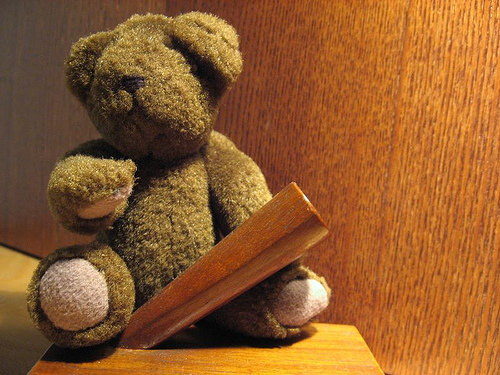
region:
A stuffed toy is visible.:
[95, 104, 209, 226]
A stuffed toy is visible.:
[55, 8, 210, 285]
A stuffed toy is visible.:
[54, 32, 175, 204]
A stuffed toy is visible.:
[91, 37, 203, 261]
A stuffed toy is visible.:
[107, 100, 192, 261]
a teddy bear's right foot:
[27, 244, 136, 351]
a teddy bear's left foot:
[252, 264, 329, 343]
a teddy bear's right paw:
[52, 155, 137, 233]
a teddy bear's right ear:
[65, 34, 114, 99]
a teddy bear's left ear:
[171, 6, 242, 93]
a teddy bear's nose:
[120, 73, 148, 95]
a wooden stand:
[30, 181, 387, 373]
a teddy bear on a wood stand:
[27, 9, 384, 374]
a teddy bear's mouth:
[110, 96, 170, 126]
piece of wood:
[122, 178, 328, 348]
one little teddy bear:
[28, 23, 402, 352]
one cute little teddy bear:
[17, 22, 390, 329]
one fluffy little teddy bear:
[18, 21, 381, 349]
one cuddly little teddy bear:
[22, 18, 407, 348]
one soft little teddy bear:
[0, 17, 395, 352]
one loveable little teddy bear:
[30, 10, 396, 342]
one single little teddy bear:
[6, 5, 366, 340]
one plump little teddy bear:
[20, 12, 355, 337]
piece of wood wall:
[325, 40, 480, 260]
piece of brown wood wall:
[351, 35, 476, 270]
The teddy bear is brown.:
[26, 8, 366, 359]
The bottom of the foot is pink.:
[40, 255, 107, 333]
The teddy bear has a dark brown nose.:
[117, 70, 145, 91]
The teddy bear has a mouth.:
[100, 92, 173, 133]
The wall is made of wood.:
[263, 46, 495, 143]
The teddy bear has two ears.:
[62, 6, 254, 101]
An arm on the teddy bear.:
[203, 135, 274, 227]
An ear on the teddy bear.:
[58, 17, 105, 97]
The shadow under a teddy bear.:
[168, 327, 284, 347]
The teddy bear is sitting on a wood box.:
[19, 6, 366, 373]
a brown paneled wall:
[327, 55, 457, 239]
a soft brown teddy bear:
[74, 19, 256, 234]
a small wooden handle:
[239, 195, 323, 271]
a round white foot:
[46, 262, 99, 329]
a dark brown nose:
[118, 72, 152, 100]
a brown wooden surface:
[206, 347, 364, 373]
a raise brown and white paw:
[54, 159, 137, 235]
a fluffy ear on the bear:
[183, 21, 250, 78]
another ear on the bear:
[69, 32, 97, 93]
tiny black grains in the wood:
[408, 120, 468, 300]